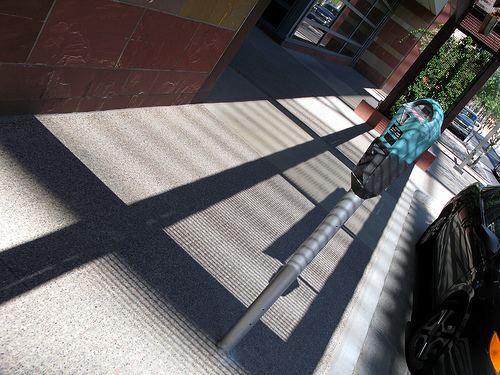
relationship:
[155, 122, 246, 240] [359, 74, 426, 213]
sidewalk with meter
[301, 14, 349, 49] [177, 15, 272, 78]
windows on building